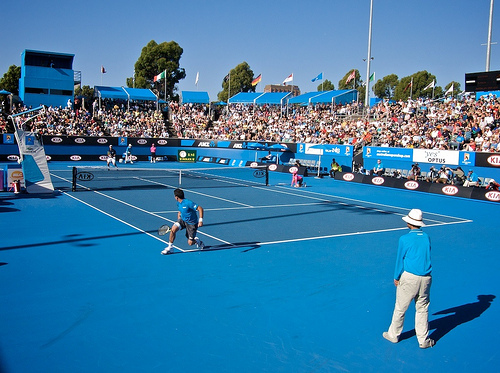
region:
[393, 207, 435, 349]
man wearing a white hat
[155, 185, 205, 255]
tennis player diving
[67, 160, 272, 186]
black tennis net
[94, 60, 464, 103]
small flags all around the court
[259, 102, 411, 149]
audience watching the game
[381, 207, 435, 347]
man wearing white pants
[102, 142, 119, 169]
tennis player wearing white shorts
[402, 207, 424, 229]
white hat with a black band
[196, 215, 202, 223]
thick white armband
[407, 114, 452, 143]
crowd sitting together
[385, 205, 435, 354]
man in blue shirt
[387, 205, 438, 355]
white hat on a man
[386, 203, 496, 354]
person casting a shadow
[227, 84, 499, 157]
crowd of people in spectator seats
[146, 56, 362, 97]
flags blowing in the wind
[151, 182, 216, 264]
man with tennis racket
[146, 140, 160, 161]
person in bright pink shirt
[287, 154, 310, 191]
tennis match line judge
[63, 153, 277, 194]
tennis net on tennis court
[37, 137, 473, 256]
blue tennis court with white lines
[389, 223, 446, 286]
this is a blue shirt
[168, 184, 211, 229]
a bright blue shirt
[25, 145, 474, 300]
a blue tennis court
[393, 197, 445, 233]
this is a white hat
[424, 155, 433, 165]
the black letter O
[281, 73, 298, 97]
this is a flag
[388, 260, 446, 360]
these are the pants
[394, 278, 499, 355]
this is a shadow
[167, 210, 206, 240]
these are the shorts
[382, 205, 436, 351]
a man watches the match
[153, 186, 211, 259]
a tennis palyer in an action pose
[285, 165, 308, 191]
a ball boy waits to get the ball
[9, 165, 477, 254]
the tennis court is deep blue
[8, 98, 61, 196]
the judge's chair by the court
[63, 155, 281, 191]
the tennis net in the court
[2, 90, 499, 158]
the crowd watches the match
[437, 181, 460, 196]
an advertisement on the wall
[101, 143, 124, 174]
the opposing player waits for the ball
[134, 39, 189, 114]
a tree and a flag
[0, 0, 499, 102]
a large area of blue sky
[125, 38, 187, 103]
a green tree in the background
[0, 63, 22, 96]
a green tree in the background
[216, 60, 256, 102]
a green tree in the background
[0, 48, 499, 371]
a blue tennis arena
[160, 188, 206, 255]
a tennis player on the court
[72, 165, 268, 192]
the tennis court's net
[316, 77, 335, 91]
a green tree in the background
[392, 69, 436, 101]
a green tree in the background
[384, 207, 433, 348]
man is standing on the court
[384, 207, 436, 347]
man is wearing a hat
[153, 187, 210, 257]
The player is lunging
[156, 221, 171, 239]
The racquet beside the leg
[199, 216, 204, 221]
The wristband on the player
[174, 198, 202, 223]
The blue shirt on the player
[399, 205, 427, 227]
The white hat on the officals head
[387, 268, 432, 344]
The white pants on the man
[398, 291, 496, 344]
The shadows on the court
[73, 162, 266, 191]
The white net over the court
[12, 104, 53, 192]
The officals booth is empty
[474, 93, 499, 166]
crowds watching from a bleacher